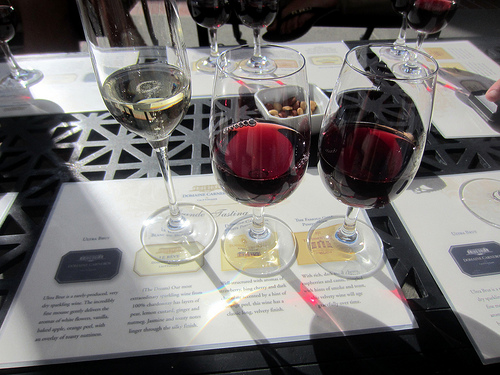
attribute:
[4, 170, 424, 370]
menu — restaurant's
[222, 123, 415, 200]
wine — red, white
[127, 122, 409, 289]
glass — sitting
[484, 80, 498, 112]
finger — person's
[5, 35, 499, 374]
table — metal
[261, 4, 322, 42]
sandal — black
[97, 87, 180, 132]
wine — white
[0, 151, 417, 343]
paper — white